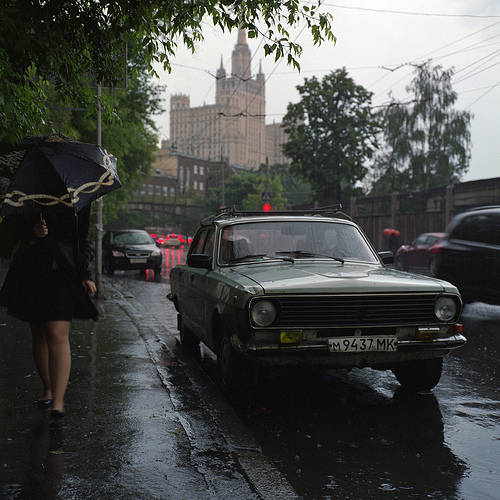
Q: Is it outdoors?
A: Yes, it is outdoors.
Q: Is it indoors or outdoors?
A: It is outdoors.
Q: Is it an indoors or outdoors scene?
A: It is outdoors.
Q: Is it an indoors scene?
A: No, it is outdoors.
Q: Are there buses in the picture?
A: No, there are no buses.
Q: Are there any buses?
A: No, there are no buses.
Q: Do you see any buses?
A: No, there are no buses.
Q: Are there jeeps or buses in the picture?
A: No, there are no buses or jeeps.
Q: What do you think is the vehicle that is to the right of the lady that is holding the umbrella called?
A: The vehicle is a car.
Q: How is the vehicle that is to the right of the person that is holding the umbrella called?
A: The vehicle is a car.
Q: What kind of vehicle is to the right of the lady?
A: The vehicle is a car.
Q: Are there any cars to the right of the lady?
A: Yes, there is a car to the right of the lady.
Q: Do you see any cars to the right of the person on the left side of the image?
A: Yes, there is a car to the right of the lady.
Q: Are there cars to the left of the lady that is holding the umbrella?
A: No, the car is to the right of the lady.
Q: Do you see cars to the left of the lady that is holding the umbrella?
A: No, the car is to the right of the lady.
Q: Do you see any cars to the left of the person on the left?
A: No, the car is to the right of the lady.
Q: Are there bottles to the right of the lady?
A: No, there is a car to the right of the lady.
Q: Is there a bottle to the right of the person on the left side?
A: No, there is a car to the right of the lady.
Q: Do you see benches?
A: No, there are no benches.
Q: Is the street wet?
A: Yes, the street is wet.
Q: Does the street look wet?
A: Yes, the street is wet.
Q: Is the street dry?
A: No, the street is wet.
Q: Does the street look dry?
A: No, the street is wet.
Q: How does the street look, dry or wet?
A: The street is wet.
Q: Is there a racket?
A: No, there are no rackets.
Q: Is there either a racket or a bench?
A: No, there are no rackets or benches.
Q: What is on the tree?
A: The leaves are on the tree.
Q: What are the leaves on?
A: The leaves are on the tree.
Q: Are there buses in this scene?
A: No, there are no buses.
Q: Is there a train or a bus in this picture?
A: No, there are no buses or trains.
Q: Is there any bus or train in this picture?
A: No, there are no buses or trains.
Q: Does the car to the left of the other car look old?
A: Yes, the car is old.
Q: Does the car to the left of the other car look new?
A: No, the car is old.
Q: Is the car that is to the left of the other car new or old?
A: The car is old.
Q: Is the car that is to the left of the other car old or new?
A: The car is old.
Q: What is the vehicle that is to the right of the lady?
A: The vehicle is a car.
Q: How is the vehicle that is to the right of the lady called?
A: The vehicle is a car.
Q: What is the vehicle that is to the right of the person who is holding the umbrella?
A: The vehicle is a car.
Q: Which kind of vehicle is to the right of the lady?
A: The vehicle is a car.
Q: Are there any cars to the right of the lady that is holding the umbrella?
A: Yes, there is a car to the right of the lady.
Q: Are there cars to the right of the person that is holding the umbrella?
A: Yes, there is a car to the right of the lady.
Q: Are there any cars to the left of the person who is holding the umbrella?
A: No, the car is to the right of the lady.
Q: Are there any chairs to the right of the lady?
A: No, there is a car to the right of the lady.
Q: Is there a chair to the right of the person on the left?
A: No, there is a car to the right of the lady.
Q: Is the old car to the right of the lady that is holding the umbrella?
A: Yes, the car is to the right of the lady.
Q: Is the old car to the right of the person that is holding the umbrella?
A: Yes, the car is to the right of the lady.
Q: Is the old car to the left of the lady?
A: No, the car is to the right of the lady.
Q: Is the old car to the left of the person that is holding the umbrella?
A: No, the car is to the right of the lady.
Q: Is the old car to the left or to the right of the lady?
A: The car is to the right of the lady.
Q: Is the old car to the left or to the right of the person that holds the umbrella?
A: The car is to the right of the lady.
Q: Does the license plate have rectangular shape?
A: Yes, the license plate is rectangular.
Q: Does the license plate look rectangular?
A: Yes, the license plate is rectangular.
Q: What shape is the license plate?
A: The license plate is rectangular.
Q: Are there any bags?
A: No, there are no bags.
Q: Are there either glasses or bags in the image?
A: No, there are no bags or glasses.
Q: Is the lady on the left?
A: Yes, the lady is on the left of the image.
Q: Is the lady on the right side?
A: No, the lady is on the left of the image.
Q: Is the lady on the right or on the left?
A: The lady is on the left of the image.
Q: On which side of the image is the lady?
A: The lady is on the left of the image.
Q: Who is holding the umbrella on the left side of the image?
A: The lady is holding the umbrella.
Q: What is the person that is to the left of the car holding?
A: The lady is holding the umbrella.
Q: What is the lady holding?
A: The lady is holding the umbrella.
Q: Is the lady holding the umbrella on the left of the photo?
A: Yes, the lady is holding the umbrella.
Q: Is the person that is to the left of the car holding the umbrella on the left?
A: Yes, the lady is holding the umbrella.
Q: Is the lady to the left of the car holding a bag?
A: No, the lady is holding the umbrella.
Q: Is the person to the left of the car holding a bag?
A: No, the lady is holding the umbrella.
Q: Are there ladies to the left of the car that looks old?
A: Yes, there is a lady to the left of the car.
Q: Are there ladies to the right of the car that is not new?
A: No, the lady is to the left of the car.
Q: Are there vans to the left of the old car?
A: No, there is a lady to the left of the car.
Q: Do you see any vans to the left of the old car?
A: No, there is a lady to the left of the car.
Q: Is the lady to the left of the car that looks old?
A: Yes, the lady is to the left of the car.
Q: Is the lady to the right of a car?
A: No, the lady is to the left of a car.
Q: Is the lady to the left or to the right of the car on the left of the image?
A: The lady is to the left of the car.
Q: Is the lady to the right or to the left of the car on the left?
A: The lady is to the left of the car.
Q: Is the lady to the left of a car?
A: Yes, the lady is to the left of a car.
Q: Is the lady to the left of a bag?
A: No, the lady is to the left of a car.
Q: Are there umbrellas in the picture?
A: Yes, there is an umbrella.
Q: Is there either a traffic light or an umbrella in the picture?
A: Yes, there is an umbrella.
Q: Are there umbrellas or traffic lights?
A: Yes, there is an umbrella.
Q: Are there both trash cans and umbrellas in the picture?
A: No, there is an umbrella but no trash cans.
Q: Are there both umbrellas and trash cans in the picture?
A: No, there is an umbrella but no trash cans.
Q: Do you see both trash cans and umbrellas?
A: No, there is an umbrella but no trash cans.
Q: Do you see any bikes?
A: No, there are no bikes.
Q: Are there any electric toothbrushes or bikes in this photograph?
A: No, there are no bikes or electric toothbrushes.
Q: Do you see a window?
A: Yes, there is a window.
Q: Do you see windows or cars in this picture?
A: Yes, there is a window.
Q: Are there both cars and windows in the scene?
A: Yes, there are both a window and a car.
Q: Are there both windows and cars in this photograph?
A: Yes, there are both a window and a car.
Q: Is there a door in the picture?
A: No, there are no doors.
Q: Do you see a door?
A: No, there are no doors.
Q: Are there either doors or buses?
A: No, there are no doors or buses.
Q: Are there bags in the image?
A: No, there are no bags.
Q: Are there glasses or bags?
A: No, there are no bags or glasses.